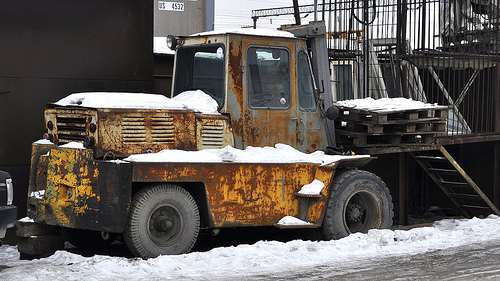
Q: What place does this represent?
A: It represents the street.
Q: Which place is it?
A: It is a street.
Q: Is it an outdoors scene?
A: Yes, it is outdoors.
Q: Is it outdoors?
A: Yes, it is outdoors.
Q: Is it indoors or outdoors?
A: It is outdoors.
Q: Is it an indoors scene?
A: No, it is outdoors.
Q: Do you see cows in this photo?
A: No, there are no cows.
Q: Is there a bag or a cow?
A: No, there are no cows or bags.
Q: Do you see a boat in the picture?
A: No, there are no boats.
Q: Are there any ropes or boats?
A: No, there are no boats or ropes.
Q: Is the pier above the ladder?
A: Yes, the pier is above the ladder.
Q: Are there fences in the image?
A: Yes, there is a fence.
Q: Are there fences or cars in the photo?
A: Yes, there is a fence.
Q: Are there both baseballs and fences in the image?
A: No, there is a fence but no baseballs.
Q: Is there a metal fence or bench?
A: Yes, there is a metal fence.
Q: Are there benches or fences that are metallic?
A: Yes, the fence is metallic.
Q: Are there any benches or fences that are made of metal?
A: Yes, the fence is made of metal.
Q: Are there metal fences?
A: Yes, there is a metal fence.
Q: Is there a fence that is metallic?
A: Yes, there is a fence that is metallic.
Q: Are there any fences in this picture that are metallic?
A: Yes, there is a fence that is metallic.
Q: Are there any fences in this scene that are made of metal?
A: Yes, there is a fence that is made of metal.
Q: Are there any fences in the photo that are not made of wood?
A: Yes, there is a fence that is made of metal.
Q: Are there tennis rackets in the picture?
A: No, there are no tennis rackets.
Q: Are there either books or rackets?
A: No, there are no rackets or books.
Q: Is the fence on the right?
A: Yes, the fence is on the right of the image.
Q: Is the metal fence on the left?
A: No, the fence is on the right of the image.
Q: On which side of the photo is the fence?
A: The fence is on the right of the image.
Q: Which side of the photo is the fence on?
A: The fence is on the right of the image.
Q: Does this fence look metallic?
A: Yes, the fence is metallic.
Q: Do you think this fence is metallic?
A: Yes, the fence is metallic.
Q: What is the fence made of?
A: The fence is made of metal.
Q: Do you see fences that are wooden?
A: No, there is a fence but it is metallic.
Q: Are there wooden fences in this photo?
A: No, there is a fence but it is metallic.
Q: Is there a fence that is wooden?
A: No, there is a fence but it is metallic.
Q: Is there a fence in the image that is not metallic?
A: No, there is a fence but it is metallic.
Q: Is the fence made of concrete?
A: No, the fence is made of metal.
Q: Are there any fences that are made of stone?
A: No, there is a fence but it is made of metal.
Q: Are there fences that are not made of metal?
A: No, there is a fence but it is made of metal.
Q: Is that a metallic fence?
A: Yes, that is a metallic fence.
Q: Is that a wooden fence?
A: No, that is a metallic fence.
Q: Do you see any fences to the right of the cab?
A: Yes, there is a fence to the right of the cab.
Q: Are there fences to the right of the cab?
A: Yes, there is a fence to the right of the cab.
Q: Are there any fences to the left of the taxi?
A: No, the fence is to the right of the taxi.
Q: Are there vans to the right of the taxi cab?
A: No, there is a fence to the right of the taxi cab.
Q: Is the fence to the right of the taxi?
A: Yes, the fence is to the right of the taxi.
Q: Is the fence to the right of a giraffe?
A: No, the fence is to the right of the taxi.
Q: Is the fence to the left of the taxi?
A: No, the fence is to the right of the taxi.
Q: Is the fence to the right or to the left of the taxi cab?
A: The fence is to the right of the taxi cab.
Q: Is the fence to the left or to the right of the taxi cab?
A: The fence is to the right of the taxi cab.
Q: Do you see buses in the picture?
A: No, there are no buses.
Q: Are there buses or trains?
A: No, there are no buses or trains.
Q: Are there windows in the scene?
A: Yes, there is a window.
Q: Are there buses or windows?
A: Yes, there is a window.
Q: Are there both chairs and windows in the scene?
A: No, there is a window but no chairs.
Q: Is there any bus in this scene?
A: No, there are no buses.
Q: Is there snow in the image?
A: Yes, there is snow.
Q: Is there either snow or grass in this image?
A: Yes, there is snow.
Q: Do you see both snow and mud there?
A: No, there is snow but no mud.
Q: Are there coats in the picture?
A: No, there are no coats.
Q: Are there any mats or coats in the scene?
A: No, there are no coats or mats.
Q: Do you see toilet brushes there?
A: No, there are no toilet brushes.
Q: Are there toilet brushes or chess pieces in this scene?
A: No, there are no toilet brushes or chess pieces.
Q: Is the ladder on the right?
A: Yes, the ladder is on the right of the image.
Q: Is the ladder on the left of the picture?
A: No, the ladder is on the right of the image.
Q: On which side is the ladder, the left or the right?
A: The ladder is on the right of the image.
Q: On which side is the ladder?
A: The ladder is on the right of the image.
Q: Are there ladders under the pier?
A: Yes, there is a ladder under the pier.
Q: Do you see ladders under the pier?
A: Yes, there is a ladder under the pier.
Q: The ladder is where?
A: The ladder is on the snow.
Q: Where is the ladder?
A: The ladder is on the snow.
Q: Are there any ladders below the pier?
A: Yes, there is a ladder below the pier.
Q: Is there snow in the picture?
A: Yes, there is snow.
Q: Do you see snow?
A: Yes, there is snow.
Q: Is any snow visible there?
A: Yes, there is snow.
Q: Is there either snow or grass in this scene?
A: Yes, there is snow.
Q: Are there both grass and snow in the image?
A: No, there is snow but no grass.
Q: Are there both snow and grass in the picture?
A: No, there is snow but no grass.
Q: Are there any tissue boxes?
A: No, there are no tissue boxes.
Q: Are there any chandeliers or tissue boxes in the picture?
A: No, there are no tissue boxes or chandeliers.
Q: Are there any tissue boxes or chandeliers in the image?
A: No, there are no tissue boxes or chandeliers.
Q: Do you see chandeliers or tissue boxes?
A: No, there are no tissue boxes or chandeliers.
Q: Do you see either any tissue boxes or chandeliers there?
A: No, there are no tissue boxes or chandeliers.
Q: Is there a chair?
A: No, there are no chairs.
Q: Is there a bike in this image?
A: No, there are no bikes.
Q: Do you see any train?
A: No, there are no trains.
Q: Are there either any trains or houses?
A: No, there are no trains or houses.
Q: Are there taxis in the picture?
A: Yes, there is a taxi.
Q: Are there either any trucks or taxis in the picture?
A: Yes, there is a taxi.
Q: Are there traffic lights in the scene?
A: No, there are no traffic lights.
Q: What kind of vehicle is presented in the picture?
A: The vehicle is a taxi.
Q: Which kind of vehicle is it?
A: The vehicle is a taxi.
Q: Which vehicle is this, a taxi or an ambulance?
A: That is a taxi.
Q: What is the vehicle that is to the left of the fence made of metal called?
A: The vehicle is a taxi.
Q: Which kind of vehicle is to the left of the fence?
A: The vehicle is a taxi.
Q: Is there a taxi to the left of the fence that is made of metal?
A: Yes, there is a taxi to the left of the fence.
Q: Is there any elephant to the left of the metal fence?
A: No, there is a taxi to the left of the fence.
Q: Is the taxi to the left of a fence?
A: Yes, the taxi is to the left of a fence.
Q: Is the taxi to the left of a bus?
A: No, the taxi is to the left of a fence.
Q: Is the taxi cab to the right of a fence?
A: No, the taxi cab is to the left of a fence.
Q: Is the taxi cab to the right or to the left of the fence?
A: The taxi cab is to the left of the fence.